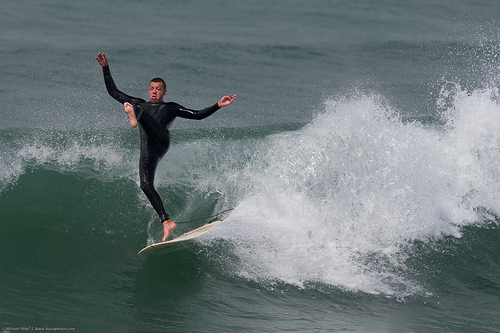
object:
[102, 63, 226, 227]
wetsuit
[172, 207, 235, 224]
rope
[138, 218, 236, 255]
surfboard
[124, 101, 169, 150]
leg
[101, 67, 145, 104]
arm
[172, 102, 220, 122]
arm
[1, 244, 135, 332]
water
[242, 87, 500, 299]
wave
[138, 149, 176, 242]
left leg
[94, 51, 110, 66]
hand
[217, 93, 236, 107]
hand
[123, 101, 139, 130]
right foot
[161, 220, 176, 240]
left foot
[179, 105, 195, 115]
left bicep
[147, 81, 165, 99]
face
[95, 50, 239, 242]
man